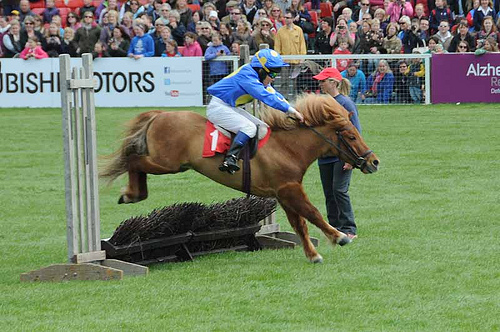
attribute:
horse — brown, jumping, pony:
[98, 90, 381, 266]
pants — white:
[207, 96, 268, 140]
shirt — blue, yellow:
[204, 64, 289, 114]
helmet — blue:
[250, 46, 290, 69]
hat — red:
[311, 65, 344, 81]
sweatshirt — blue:
[316, 89, 362, 163]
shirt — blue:
[128, 33, 158, 58]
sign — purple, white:
[428, 50, 499, 103]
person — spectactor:
[204, 33, 232, 80]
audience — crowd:
[1, 0, 498, 102]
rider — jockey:
[207, 47, 306, 176]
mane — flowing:
[254, 93, 348, 129]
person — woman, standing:
[309, 67, 363, 247]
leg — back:
[116, 169, 140, 208]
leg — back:
[136, 170, 150, 204]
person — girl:
[18, 35, 51, 60]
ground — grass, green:
[0, 106, 499, 328]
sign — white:
[1, 57, 204, 108]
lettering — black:
[0, 70, 158, 96]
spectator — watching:
[382, 21, 402, 52]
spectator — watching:
[249, 16, 276, 47]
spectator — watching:
[72, 10, 102, 54]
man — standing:
[274, 9, 312, 95]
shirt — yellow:
[272, 25, 308, 62]